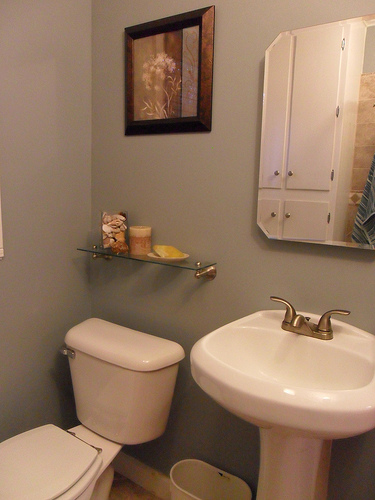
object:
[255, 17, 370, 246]
cabinet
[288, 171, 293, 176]
door handle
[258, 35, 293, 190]
cabinet door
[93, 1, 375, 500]
wall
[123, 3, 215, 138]
frame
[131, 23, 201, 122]
picture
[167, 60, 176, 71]
flower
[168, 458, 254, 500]
waste basket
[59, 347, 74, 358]
handle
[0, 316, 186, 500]
toilet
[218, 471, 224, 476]
spot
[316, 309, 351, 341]
faucet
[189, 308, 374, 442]
sink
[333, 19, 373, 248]
mirror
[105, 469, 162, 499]
floor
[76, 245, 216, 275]
shelf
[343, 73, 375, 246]
reflection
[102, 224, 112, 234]
shell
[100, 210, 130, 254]
jar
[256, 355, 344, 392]
bottom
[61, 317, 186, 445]
tank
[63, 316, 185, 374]
top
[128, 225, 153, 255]
candle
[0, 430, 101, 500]
toilet bowl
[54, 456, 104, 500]
toilet seat